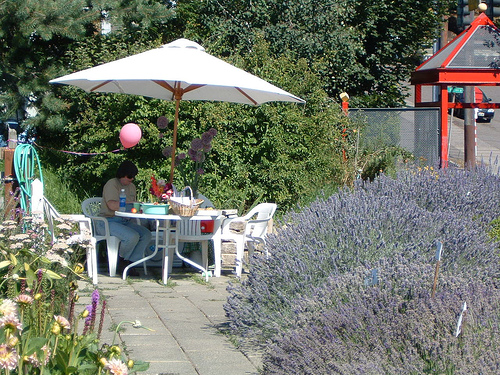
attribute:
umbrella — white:
[68, 46, 310, 106]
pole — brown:
[151, 123, 212, 200]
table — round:
[107, 200, 199, 269]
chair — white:
[242, 180, 292, 267]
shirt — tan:
[89, 196, 174, 231]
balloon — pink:
[89, 82, 158, 162]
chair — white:
[203, 184, 310, 283]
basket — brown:
[171, 159, 239, 249]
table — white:
[87, 184, 172, 239]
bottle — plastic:
[105, 182, 155, 217]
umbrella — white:
[47, 43, 230, 113]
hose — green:
[10, 148, 68, 208]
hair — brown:
[89, 165, 148, 180]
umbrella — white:
[97, 45, 281, 114]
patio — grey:
[85, 291, 245, 366]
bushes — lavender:
[337, 228, 478, 367]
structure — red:
[429, 53, 467, 153]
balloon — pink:
[109, 127, 129, 141]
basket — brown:
[151, 159, 211, 271]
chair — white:
[207, 144, 289, 299]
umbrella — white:
[93, 34, 308, 124]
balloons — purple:
[167, 122, 248, 188]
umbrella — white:
[83, 67, 313, 129]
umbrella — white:
[50, 31, 328, 136]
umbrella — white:
[41, 26, 322, 144]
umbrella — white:
[38, 24, 312, 160]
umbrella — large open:
[39, 17, 306, 138]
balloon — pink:
[110, 119, 148, 160]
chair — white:
[205, 190, 297, 300]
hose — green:
[0, 140, 67, 214]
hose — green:
[1, 131, 73, 249]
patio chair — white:
[199, 193, 302, 322]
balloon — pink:
[104, 107, 148, 150]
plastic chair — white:
[207, 170, 294, 289]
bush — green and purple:
[221, 130, 482, 372]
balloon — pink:
[102, 110, 157, 167]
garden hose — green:
[2, 130, 55, 229]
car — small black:
[440, 79, 490, 133]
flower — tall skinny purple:
[67, 280, 112, 340]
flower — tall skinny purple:
[78, 295, 112, 343]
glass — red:
[450, 73, 480, 153]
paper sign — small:
[425, 215, 458, 300]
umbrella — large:
[45, 19, 305, 123]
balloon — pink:
[116, 100, 146, 143]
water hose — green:
[14, 131, 52, 206]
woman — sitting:
[100, 160, 156, 264]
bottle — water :
[110, 188, 131, 213]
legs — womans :
[99, 226, 149, 289]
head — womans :
[108, 164, 144, 189]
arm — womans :
[100, 181, 134, 213]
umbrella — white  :
[45, 25, 307, 132]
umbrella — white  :
[41, 31, 314, 126]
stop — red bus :
[330, 88, 363, 183]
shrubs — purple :
[10, 262, 120, 363]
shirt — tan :
[98, 177, 138, 213]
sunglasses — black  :
[115, 169, 129, 180]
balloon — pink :
[118, 120, 149, 151]